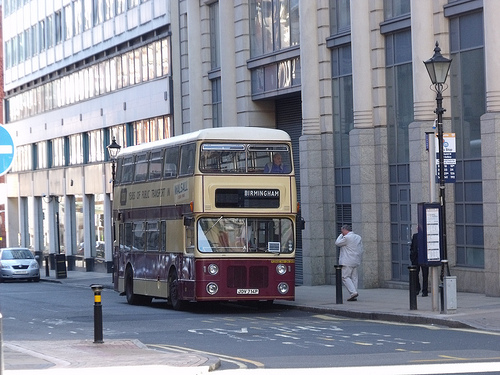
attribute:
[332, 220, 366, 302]
man — walking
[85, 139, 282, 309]
windows — long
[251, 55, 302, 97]
window — gray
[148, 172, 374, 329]
windows — large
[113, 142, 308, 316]
bus — double decker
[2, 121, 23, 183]
sign — blue 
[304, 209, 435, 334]
man — white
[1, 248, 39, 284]
car — silver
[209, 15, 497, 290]
house — window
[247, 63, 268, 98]
window — house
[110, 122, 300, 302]
bus — red, bottom, double-decker, double decker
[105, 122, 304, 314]
bus — double decker